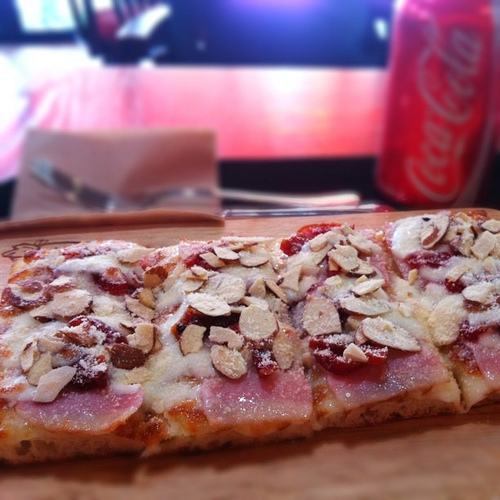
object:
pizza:
[0, 210, 500, 468]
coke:
[394, 9, 485, 203]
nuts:
[186, 291, 232, 316]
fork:
[31, 158, 358, 208]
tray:
[0, 207, 500, 500]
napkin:
[0, 126, 222, 226]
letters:
[446, 27, 482, 60]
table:
[0, 64, 383, 173]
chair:
[68, 0, 169, 57]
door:
[10, 0, 72, 46]